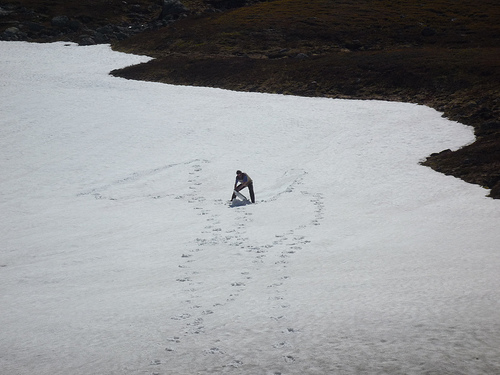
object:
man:
[231, 169, 257, 205]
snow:
[66, 109, 123, 131]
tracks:
[219, 211, 309, 288]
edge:
[281, 91, 385, 102]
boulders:
[61, 27, 113, 41]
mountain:
[334, 37, 500, 76]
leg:
[231, 183, 246, 203]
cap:
[235, 170, 242, 175]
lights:
[126, 24, 135, 29]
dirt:
[204, 73, 227, 86]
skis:
[233, 188, 252, 205]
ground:
[10, 83, 37, 97]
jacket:
[235, 173, 253, 186]